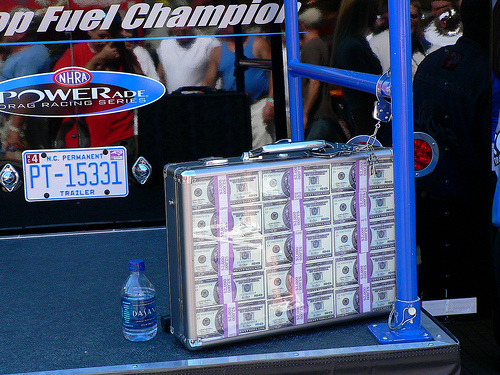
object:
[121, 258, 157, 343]
bottle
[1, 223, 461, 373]
table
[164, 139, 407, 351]
briefcase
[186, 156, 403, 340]
money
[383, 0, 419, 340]
pole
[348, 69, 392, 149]
handcuffs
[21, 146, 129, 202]
plate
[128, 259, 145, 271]
top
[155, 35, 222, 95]
shirt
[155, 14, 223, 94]
man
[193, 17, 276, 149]
man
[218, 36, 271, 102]
shirt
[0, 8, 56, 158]
man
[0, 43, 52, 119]
shirt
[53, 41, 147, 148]
shirt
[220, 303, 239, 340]
money bands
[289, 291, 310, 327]
money bands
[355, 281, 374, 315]
money bands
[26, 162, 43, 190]
letters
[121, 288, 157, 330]
label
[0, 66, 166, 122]
advertisment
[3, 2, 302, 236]
glass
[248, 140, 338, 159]
handle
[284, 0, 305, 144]
pole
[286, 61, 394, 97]
pole